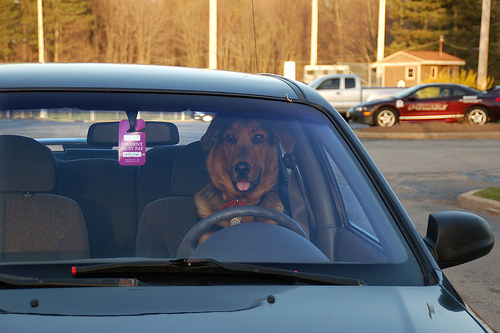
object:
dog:
[193, 117, 295, 253]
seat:
[134, 139, 210, 257]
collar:
[219, 201, 256, 222]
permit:
[117, 119, 147, 166]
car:
[0, 62, 498, 332]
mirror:
[88, 113, 178, 146]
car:
[345, 82, 499, 124]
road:
[348, 113, 500, 332]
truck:
[307, 72, 413, 113]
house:
[371, 42, 465, 87]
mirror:
[422, 212, 492, 270]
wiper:
[70, 257, 359, 286]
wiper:
[1, 273, 97, 286]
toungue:
[236, 181, 251, 192]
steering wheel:
[176, 203, 309, 258]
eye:
[252, 134, 266, 145]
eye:
[224, 134, 238, 145]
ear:
[198, 112, 230, 149]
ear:
[275, 122, 297, 155]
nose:
[236, 163, 251, 176]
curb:
[456, 189, 499, 209]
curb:
[357, 127, 499, 141]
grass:
[476, 191, 500, 200]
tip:
[70, 268, 77, 276]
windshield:
[2, 92, 424, 287]